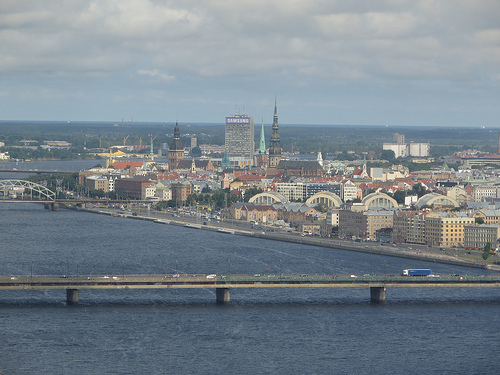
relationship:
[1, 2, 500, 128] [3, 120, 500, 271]
sky above land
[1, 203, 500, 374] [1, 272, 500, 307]
water next to bridge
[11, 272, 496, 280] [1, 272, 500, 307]
cars on bridge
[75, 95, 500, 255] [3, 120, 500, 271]
buildings on top of land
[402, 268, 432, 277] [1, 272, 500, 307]
truck on top of bridge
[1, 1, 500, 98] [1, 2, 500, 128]
clouds in sky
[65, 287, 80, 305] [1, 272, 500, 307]
pillar below bridge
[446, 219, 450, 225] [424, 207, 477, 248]
window on building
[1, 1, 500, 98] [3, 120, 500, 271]
clouds above land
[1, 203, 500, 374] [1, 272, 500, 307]
water below bridge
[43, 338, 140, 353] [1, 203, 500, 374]
ripples in water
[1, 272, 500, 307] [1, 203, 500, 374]
bridge above water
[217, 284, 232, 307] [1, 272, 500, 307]
pillar under bridge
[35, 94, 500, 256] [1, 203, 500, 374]
city next to water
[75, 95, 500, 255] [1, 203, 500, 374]
buildings near water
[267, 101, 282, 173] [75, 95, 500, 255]
tower in middle of buildings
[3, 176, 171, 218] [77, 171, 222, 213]
bridge in middle of houses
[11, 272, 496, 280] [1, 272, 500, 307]
cars on top of bridge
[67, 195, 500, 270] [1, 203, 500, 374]
street next to water